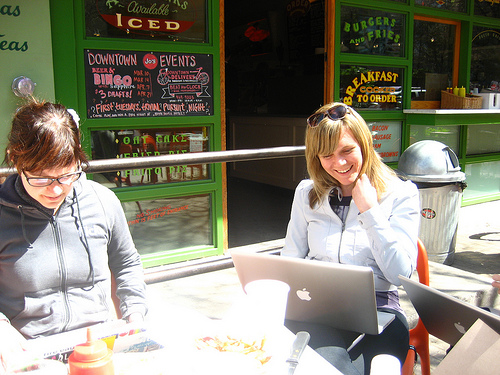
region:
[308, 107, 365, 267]
woman with sunglasses on her head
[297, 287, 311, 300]
Macintosh apple on a laptop cover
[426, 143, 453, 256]
silver metal garbage can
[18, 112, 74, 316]
woman wearing glasses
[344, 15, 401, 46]
window sign for BURGERS AND FRIES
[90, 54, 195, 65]
painted window sign for DOWNTOWN EVENTS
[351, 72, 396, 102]
painted sign for Breakfast Cooked to Order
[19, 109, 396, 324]
two women sitting outside at a table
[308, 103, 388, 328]
woman wearing a white zippered jacket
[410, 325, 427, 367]
orange chair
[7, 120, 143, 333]
"Her hoodie is zipped up"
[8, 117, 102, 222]
"She is wearing glasses"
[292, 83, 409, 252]
"Her sunglasses are on her head"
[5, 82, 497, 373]
"They are sitting at a table"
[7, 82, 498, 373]
"Everyone has a laptop"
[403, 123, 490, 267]
"A large metal trash can"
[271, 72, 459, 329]
"Her jacket is zipped"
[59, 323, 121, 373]
"A bottle of ketchup"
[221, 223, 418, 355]
"The laptop is opened"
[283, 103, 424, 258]
"The woman is smiling"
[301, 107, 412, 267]
this is a lady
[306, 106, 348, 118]
this is a spectacle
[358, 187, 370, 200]
the lady is light skinned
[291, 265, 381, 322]
this is a laptop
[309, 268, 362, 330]
the laptop is grey in color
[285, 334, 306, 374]
this is a knife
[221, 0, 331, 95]
this is a door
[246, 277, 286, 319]
this is a container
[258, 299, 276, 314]
the container is white in color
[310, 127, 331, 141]
the hair is scale brown in color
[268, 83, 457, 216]
a smiling woman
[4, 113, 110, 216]
woman with glasses on head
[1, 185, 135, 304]
gray sweater on girl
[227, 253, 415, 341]
silver laptop on person's lap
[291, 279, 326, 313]
apple logo on laptop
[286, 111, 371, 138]
sunglasses on woman's head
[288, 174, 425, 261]
white jacket on girl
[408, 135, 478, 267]
waste bin behind girl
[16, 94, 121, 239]
woman with glasses looking down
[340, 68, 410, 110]
yellow letters that say "breakfast"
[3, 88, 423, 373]
two ladies sitting at a table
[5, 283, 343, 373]
the table is outside in the sun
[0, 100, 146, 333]
the lady has a gray hoodie on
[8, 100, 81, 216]
the girl is wearing reading glasses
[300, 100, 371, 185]
the girl has sunglasses on top of her head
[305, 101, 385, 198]
the girl is smiling at her laptop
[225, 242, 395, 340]
a silver laptop is open on the table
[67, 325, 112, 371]
a squeeze bottle of mustard is on the table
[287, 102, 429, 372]
the lady is sitting in an orange chair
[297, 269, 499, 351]
another laptop is next to the lady's laptop